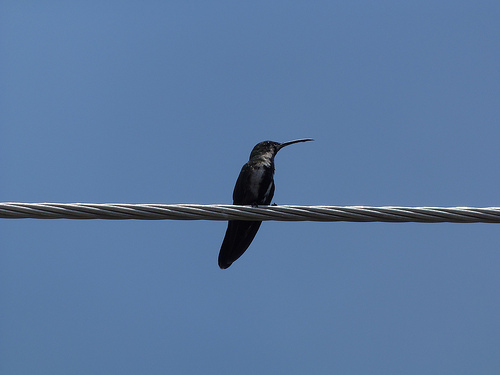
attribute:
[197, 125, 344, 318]
bird — sitting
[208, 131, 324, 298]
black bird — sitting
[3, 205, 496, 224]
wire — silver 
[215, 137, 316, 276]
bird — silver , black , shiny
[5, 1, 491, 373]
sky — blue , cloudless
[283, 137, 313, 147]
beak — long 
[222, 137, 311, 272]
bird — two toned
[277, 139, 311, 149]
beak — Long , black 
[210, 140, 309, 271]
bird — black 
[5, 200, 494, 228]
wire — coiled 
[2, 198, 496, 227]
wire — silver 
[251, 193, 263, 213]
foot — small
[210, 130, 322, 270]
bird — black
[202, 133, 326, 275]
bird — black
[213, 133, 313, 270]
bird — black